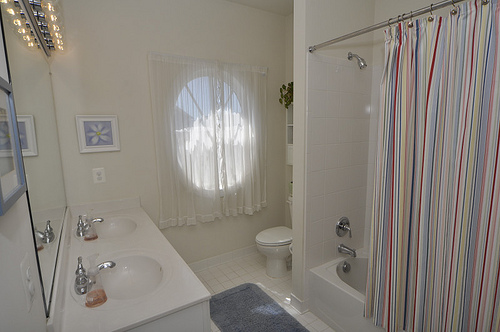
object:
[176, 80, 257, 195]
window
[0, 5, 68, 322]
mirror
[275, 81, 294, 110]
plant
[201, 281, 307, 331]
bath rug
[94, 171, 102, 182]
electrical socket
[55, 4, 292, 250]
wall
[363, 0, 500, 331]
shower curtain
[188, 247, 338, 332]
floor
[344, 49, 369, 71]
shower head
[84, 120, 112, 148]
daisy flower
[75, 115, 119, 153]
frame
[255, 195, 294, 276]
toilet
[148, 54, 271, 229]
curtain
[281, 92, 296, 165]
cabinet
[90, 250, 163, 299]
sink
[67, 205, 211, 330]
vanity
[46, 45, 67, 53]
lights